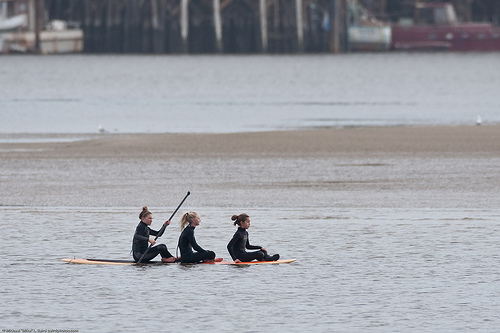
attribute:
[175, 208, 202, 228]
hair — blonde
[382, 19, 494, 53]
boat — red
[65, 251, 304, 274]
paddle board — very long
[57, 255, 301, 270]
board — orange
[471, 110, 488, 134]
buoy — small 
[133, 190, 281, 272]
girls — three, sitting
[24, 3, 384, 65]
pylons — wooden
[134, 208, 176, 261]
woman — in the back 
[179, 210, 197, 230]
hair — blonde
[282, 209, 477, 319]
water — brown 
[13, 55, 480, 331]
water — large, shallow, choppy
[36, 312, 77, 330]
water — gray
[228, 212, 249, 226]
hair — brown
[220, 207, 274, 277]
women — sitting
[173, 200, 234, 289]
women — sitting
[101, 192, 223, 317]
women — sitting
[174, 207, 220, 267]
woman — blond 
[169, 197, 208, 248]
hair — in a ponytail